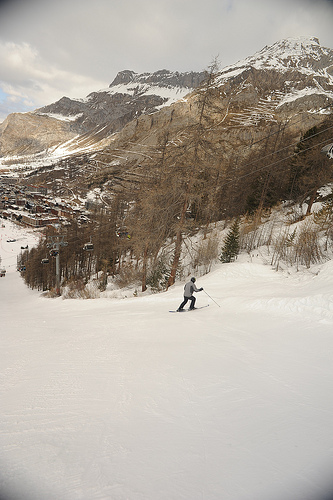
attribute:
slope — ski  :
[17, 275, 260, 337]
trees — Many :
[44, 121, 299, 259]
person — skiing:
[170, 276, 204, 311]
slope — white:
[2, 314, 332, 498]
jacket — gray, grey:
[183, 280, 201, 298]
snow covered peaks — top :
[245, 34, 333, 72]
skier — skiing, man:
[167, 277, 211, 314]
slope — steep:
[1, 239, 21, 500]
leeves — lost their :
[118, 96, 222, 276]